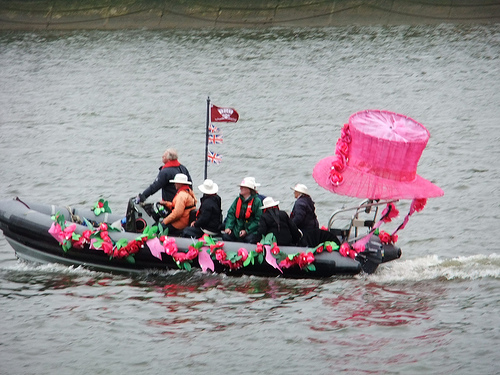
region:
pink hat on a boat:
[315, 108, 434, 205]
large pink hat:
[315, 99, 440, 206]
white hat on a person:
[295, 185, 305, 192]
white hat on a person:
[240, 178, 257, 190]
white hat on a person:
[171, 172, 196, 187]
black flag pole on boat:
[199, 98, 209, 185]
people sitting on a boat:
[143, 146, 320, 252]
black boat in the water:
[0, 93, 457, 310]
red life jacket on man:
[160, 158, 181, 168]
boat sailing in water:
[0, 75, 468, 312]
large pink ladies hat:
[311, 108, 444, 197]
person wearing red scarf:
[221, 178, 263, 243]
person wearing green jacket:
[221, 176, 263, 242]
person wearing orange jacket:
[155, 172, 197, 236]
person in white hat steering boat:
[153, 171, 197, 236]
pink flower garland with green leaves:
[48, 195, 400, 271]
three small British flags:
[207, 122, 223, 164]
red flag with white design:
[210, 105, 238, 122]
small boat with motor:
[1, 193, 401, 277]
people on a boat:
[136, 150, 321, 245]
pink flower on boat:
[303, 252, 314, 267]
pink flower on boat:
[269, 242, 281, 257]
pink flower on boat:
[233, 246, 247, 260]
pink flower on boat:
[211, 246, 225, 261]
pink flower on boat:
[183, 244, 198, 261]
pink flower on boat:
[171, 250, 186, 262]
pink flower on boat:
[156, 234, 165, 241]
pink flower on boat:
[137, 235, 147, 244]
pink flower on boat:
[339, 245, 350, 257]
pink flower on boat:
[379, 203, 397, 228]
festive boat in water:
[1, 92, 458, 283]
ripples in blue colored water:
[283, 56, 324, 93]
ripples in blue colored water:
[389, 55, 469, 106]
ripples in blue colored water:
[364, 312, 408, 340]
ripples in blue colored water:
[192, 315, 234, 345]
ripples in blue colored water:
[321, 288, 399, 368]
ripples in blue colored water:
[162, 308, 235, 356]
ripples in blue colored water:
[89, 312, 158, 354]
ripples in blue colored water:
[112, 78, 153, 103]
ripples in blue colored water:
[266, 62, 324, 112]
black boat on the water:
[1, 188, 408, 286]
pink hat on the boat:
[310, 100, 450, 205]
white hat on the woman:
[168, 172, 192, 187]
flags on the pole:
[203, 95, 244, 205]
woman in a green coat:
[219, 192, 267, 244]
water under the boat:
[0, 275, 487, 373]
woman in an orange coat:
[153, 185, 198, 229]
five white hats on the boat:
[171, 170, 327, 212]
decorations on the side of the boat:
[43, 221, 395, 276]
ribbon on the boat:
[189, 243, 216, 273]